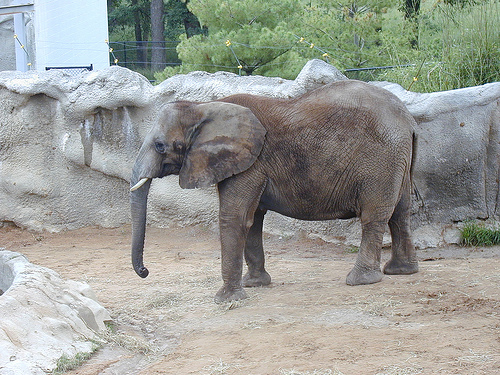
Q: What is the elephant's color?
A: Gray.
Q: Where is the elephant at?
A: Pen.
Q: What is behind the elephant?
A: Shrubs.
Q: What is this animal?
A: Elephant.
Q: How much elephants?
A: 1.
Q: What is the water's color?
A: Brown.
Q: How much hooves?
A: 4.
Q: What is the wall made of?
A: Rock.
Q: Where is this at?
A: Zoo.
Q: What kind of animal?
A: Elephant.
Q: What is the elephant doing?
A: Standing.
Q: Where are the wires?
A: Over the wall.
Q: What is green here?
A: Trees.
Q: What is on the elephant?
A: Tusks.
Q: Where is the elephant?
A: Zoo.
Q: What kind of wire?
A: Barb.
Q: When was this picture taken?
A: During the day.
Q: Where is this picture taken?
A: At a zoo.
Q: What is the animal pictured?
A: An elephant.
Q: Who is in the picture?
A: No people.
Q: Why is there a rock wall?
A: This is a zoo.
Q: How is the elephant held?
A: In an enclosement.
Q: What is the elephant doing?
A: Standing idle.